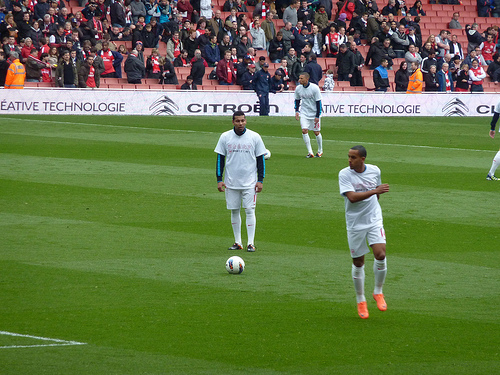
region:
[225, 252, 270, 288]
ball is white and black in color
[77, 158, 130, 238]
ground is green in color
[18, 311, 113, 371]
white lines are drawn in the ground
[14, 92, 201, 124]
boundary board is white in color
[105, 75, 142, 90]
chairs are red in color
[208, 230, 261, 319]
one ball is seen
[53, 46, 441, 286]
daytime picture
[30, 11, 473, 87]
stadium is almost full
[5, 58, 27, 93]
guards are wearing orange color dress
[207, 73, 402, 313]
Soccer players playing soccer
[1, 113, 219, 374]
A green soccer field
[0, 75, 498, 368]
Soccer players playing soccer on the soccer field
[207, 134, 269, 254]
Soccer player's uniform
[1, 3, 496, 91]
Crowd watching the soccer game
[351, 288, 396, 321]
Orange soccer cleats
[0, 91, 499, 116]
Soccer game's advertisements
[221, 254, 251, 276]
A soccer ball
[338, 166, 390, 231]
A white soccer uniform top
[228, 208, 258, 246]
Two white leg sleeves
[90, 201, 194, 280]
the grass is green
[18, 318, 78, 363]
the field lines are white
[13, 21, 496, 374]
this is soccer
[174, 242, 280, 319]
the ball is white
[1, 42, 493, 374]
it is an outdoor scene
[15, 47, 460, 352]
it is a daytime scene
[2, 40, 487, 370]
it is in a football pitch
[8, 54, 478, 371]
the game area is fenced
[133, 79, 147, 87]
the seats are red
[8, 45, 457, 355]
the weather is probably cloudy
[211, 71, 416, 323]
three men on a soccer field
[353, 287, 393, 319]
a pair of orange shoes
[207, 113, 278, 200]
a man wearing two shirts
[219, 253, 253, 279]
a white soccer ball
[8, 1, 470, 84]
a crowd of people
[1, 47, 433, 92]
two men in orange coats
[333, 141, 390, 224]
a man wearing a white t-shirt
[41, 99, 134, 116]
the word technologie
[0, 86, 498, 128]
a short white wall showing field ends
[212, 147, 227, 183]
a blue stripe on a shirt sleeve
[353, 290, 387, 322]
pair of orange shoes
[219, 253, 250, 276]
white soccer ball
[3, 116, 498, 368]
sports field of green grass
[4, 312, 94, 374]
white lines on the field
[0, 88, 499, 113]
white advertisement field barrier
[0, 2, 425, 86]
crowd of soccer fans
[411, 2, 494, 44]
brown stadium chairs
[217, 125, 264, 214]
white soccer team uniform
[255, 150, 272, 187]
blue and black shirt sleeve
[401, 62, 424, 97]
orange jacket